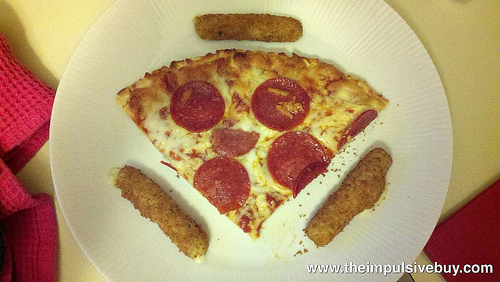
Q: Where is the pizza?
A: On the plate.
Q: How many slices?
A: One.